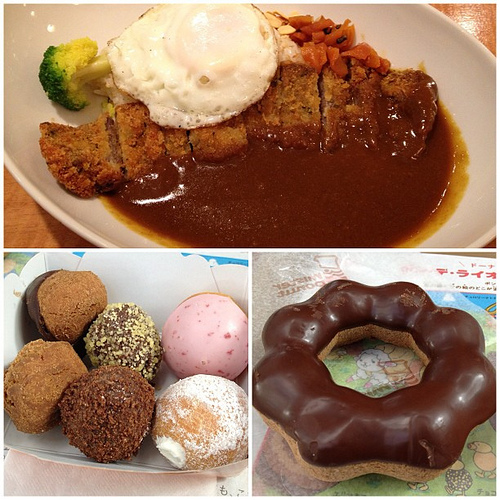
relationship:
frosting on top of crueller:
[252, 280, 496, 467] [253, 281, 499, 482]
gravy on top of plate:
[99, 60, 469, 248] [0, 0, 497, 248]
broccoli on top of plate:
[38, 37, 110, 110] [0, 0, 497, 248]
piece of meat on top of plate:
[40, 115, 122, 196] [0, 0, 497, 248]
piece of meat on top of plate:
[117, 103, 166, 176] [0, 0, 497, 248]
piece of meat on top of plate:
[190, 127, 248, 161] [0, 0, 497, 248]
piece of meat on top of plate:
[323, 67, 378, 155] [0, 0, 497, 248]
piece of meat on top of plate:
[383, 73, 437, 160] [0, 0, 497, 248]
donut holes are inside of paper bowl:
[3, 270, 249, 471] [0, 251, 250, 473]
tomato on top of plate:
[272, 16, 390, 79] [0, 0, 497, 248]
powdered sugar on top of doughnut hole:
[153, 374, 248, 468] [155, 375, 250, 469]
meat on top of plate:
[40, 115, 122, 196] [0, 0, 497, 248]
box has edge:
[0, 251, 250, 473] [1, 250, 248, 280]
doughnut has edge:
[253, 281, 499, 482] [295, 445, 458, 485]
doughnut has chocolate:
[253, 281, 499, 482] [252, 280, 496, 467]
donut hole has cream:
[155, 375, 250, 469] [155, 437, 185, 470]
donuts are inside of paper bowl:
[3, 270, 249, 471] [0, 251, 250, 473]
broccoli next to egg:
[38, 37, 110, 110] [108, 2, 279, 129]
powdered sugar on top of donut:
[153, 374, 248, 468] [155, 375, 250, 469]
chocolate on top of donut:
[252, 280, 496, 467] [253, 281, 499, 482]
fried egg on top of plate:
[108, 2, 279, 129] [0, 0, 497, 248]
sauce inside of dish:
[99, 60, 469, 248] [0, 0, 497, 248]